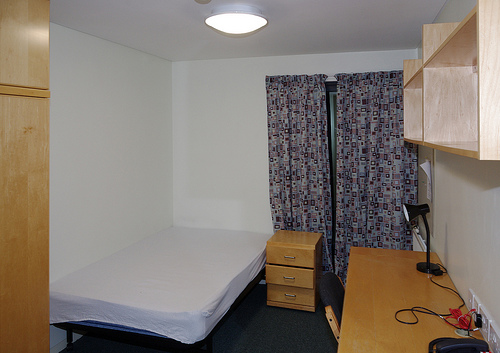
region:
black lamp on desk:
[401, 204, 446, 273]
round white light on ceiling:
[204, 7, 266, 34]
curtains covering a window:
[265, 73, 411, 297]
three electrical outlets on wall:
[465, 292, 499, 352]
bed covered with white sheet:
[48, 230, 269, 352]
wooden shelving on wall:
[401, 0, 495, 160]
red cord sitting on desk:
[444, 304, 480, 329]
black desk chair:
[319, 269, 340, 336]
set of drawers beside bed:
[266, 228, 322, 310]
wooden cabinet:
[1, 2, 48, 352]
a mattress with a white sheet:
[48, 222, 273, 343]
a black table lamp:
[399, 203, 450, 274]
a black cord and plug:
[391, 270, 486, 336]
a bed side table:
[263, 228, 323, 313]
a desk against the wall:
[336, 245, 488, 350]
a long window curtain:
[264, 73, 334, 273]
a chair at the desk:
[316, 265, 346, 339]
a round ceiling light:
[203, 10, 273, 35]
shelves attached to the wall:
[399, 0, 496, 163]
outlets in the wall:
[468, 288, 498, 350]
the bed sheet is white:
[61, 240, 202, 337]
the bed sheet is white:
[116, 208, 241, 316]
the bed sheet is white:
[202, 199, 288, 304]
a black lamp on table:
[385, 191, 470, 315]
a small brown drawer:
[265, 226, 332, 313]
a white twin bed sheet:
[42, 215, 269, 344]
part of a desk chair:
[310, 269, 342, 334]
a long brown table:
[337, 245, 476, 351]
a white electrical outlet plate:
[483, 319, 498, 345]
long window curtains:
[268, 71, 338, 278]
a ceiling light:
[202, 12, 270, 43]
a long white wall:
[172, 61, 269, 233]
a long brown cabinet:
[0, 2, 56, 352]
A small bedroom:
[8, 7, 495, 351]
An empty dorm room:
[6, 18, 495, 351]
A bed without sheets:
[59, 199, 284, 344]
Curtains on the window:
[260, 57, 425, 254]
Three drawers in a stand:
[264, 220, 316, 315]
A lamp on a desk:
[398, 195, 448, 282]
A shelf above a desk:
[391, 15, 497, 167]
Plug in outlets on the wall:
[460, 289, 496, 351]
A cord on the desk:
[388, 275, 475, 345]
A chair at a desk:
[312, 260, 349, 332]